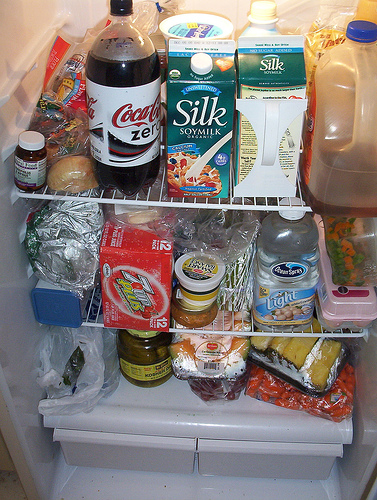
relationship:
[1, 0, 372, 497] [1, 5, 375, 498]
picture inside fridge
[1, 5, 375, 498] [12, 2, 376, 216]
fridge has top rack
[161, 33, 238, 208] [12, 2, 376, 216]
soy milk carton on top rack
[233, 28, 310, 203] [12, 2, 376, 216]
soy milk carton on top rack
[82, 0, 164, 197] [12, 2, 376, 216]
coca cola on top rack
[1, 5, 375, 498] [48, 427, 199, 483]
fridge has drawer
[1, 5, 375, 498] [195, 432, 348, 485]
fridge has drawer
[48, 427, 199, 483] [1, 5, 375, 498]
drawer in bottom of fridge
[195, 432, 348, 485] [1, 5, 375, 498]
drawer in bottom of fridge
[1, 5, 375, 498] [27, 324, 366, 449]
fridge has bottom rack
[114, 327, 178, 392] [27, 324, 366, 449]
pickle on bottom rack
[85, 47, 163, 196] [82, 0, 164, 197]
coca cola in coca cola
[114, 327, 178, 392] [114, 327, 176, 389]
pickle in jar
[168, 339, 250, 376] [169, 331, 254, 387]
cantaloupe in package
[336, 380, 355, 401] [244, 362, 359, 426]
baby carrot in bag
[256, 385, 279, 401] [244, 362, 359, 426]
baby carrot in bag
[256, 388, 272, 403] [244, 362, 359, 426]
baby carrot in bag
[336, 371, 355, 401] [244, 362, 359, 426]
baby carrot in bag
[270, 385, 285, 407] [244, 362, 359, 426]
baby carrot in bag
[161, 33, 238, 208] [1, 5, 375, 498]
soy milk carton in fridge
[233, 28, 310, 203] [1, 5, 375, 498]
soy milk carton in fridge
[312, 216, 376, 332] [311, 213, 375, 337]
eggs are in egg case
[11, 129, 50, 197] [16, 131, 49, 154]
bottle has cap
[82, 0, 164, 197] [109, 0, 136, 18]
coca cola has cap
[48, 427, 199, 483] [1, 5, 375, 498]
drawer left of fridge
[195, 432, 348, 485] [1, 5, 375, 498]
drawer right of fridge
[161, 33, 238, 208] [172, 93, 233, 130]
soy milk carton says silk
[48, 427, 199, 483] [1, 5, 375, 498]
drawer on bottom of fridge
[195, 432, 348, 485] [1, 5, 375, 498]
drawer on bottom of fridge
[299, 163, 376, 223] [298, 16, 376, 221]
tea in jug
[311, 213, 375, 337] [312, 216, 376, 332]
egg case for eggs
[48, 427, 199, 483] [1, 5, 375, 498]
drawer in fridge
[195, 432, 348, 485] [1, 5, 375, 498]
drawer in fridge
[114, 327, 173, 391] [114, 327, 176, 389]
pickle in jar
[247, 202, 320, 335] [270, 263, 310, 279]
bottle says oceanspray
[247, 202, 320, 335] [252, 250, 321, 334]
bottle contains juice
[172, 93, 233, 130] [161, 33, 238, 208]
silk on soy milk carton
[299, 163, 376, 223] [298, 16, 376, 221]
chocolate milk in jug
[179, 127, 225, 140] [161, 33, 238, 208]
soy milk in carton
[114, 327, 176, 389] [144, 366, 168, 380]
jar shows kosher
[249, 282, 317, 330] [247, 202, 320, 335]
cranberry juice in bottle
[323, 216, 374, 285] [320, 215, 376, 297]
mixed vegetables are in bag